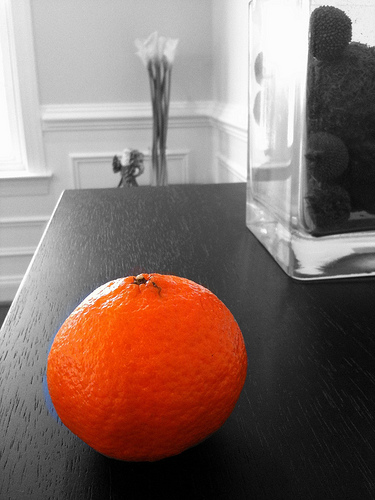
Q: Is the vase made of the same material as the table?
A: No, the vase is made of glass and the table is made of wood.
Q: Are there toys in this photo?
A: No, there are no toys.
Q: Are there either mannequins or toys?
A: No, there are no toys or mannequins.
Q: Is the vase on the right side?
A: Yes, the vase is on the right of the image.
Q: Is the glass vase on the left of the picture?
A: No, the vase is on the right of the image.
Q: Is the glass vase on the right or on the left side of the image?
A: The vase is on the right of the image.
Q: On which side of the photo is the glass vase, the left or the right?
A: The vase is on the right of the image.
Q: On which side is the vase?
A: The vase is on the right of the image.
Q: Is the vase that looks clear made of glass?
A: Yes, the vase is made of glass.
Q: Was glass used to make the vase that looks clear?
A: Yes, the vase is made of glass.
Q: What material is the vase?
A: The vase is made of glass.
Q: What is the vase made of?
A: The vase is made of glass.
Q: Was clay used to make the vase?
A: No, the vase is made of glass.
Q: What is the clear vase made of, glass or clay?
A: The vase is made of glass.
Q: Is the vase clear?
A: Yes, the vase is clear.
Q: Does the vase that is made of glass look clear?
A: Yes, the vase is clear.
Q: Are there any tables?
A: Yes, there is a table.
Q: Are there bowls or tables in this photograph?
A: Yes, there is a table.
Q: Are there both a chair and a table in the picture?
A: No, there is a table but no chairs.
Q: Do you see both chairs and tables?
A: No, there is a table but no chairs.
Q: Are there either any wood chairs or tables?
A: Yes, there is a wood table.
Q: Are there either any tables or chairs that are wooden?
A: Yes, the table is wooden.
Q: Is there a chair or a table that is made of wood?
A: Yes, the table is made of wood.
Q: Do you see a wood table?
A: Yes, there is a table that is made of wood.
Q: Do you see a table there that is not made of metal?
A: Yes, there is a table that is made of wood.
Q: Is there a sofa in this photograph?
A: No, there are no sofas.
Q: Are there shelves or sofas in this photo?
A: No, there are no sofas or shelves.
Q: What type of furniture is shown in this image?
A: The furniture is a table.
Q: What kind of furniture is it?
A: The piece of furniture is a table.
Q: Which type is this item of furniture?
A: This is a table.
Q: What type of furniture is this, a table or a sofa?
A: This is a table.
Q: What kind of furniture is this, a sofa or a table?
A: This is a table.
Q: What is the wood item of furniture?
A: The piece of furniture is a table.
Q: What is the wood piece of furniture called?
A: The piece of furniture is a table.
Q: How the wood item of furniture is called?
A: The piece of furniture is a table.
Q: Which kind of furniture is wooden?
A: The furniture is a table.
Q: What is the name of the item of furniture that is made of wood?
A: The piece of furniture is a table.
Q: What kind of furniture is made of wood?
A: The furniture is a table.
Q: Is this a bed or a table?
A: This is a table.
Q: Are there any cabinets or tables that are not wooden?
A: No, there is a table but it is wooden.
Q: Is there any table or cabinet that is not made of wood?
A: No, there is a table but it is made of wood.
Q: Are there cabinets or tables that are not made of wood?
A: No, there is a table but it is made of wood.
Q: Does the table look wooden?
A: Yes, the table is wooden.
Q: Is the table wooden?
A: Yes, the table is wooden.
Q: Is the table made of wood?
A: Yes, the table is made of wood.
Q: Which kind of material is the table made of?
A: The table is made of wood.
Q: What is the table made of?
A: The table is made of wood.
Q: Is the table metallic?
A: No, the table is wooden.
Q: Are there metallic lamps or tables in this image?
A: No, there is a table but it is wooden.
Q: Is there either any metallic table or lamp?
A: No, there is a table but it is wooden.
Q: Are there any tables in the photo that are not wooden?
A: No, there is a table but it is wooden.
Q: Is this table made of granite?
A: No, the table is made of wood.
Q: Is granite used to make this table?
A: No, the table is made of wood.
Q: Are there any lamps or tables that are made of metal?
A: No, there is a table but it is made of wood.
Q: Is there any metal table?
A: No, there is a table but it is made of wood.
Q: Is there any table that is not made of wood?
A: No, there is a table but it is made of wood.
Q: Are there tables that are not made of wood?
A: No, there is a table but it is made of wood.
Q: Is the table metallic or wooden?
A: The table is wooden.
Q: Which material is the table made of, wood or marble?
A: The table is made of wood.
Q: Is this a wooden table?
A: Yes, this is a wooden table.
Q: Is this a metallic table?
A: No, this is a wooden table.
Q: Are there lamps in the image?
A: No, there are no lamps.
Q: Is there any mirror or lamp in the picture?
A: No, there are no lamps or mirrors.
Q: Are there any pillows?
A: No, there are no pillows.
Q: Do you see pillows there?
A: No, there are no pillows.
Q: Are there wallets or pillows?
A: No, there are no pillows or wallets.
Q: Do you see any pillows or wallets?
A: No, there are no pillows or wallets.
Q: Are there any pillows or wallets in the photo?
A: No, there are no pillows or wallets.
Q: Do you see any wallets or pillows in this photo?
A: No, there are no pillows or wallets.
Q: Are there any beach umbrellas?
A: No, there are no beach umbrellas.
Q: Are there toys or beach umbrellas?
A: No, there are no beach umbrellas or toys.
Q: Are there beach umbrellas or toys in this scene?
A: No, there are no beach umbrellas or toys.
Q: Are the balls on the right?
A: Yes, the balls are on the right of the image.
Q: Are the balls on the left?
A: No, the balls are on the right of the image.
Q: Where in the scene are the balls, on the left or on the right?
A: The balls are on the right of the image.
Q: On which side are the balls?
A: The balls are on the right of the image.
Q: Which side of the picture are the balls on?
A: The balls are on the right of the image.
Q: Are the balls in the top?
A: Yes, the balls are in the top of the image.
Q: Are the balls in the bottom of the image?
A: No, the balls are in the top of the image.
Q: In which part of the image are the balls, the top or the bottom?
A: The balls are in the top of the image.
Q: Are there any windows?
A: Yes, there is a window.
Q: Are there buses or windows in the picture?
A: Yes, there is a window.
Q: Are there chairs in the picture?
A: No, there are no chairs.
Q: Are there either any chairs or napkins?
A: No, there are no chairs or napkins.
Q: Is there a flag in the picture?
A: No, there are no flags.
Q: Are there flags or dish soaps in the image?
A: No, there are no flags or dish soaps.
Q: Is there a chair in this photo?
A: No, there are no chairs.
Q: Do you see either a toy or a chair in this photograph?
A: No, there are no chairs or toys.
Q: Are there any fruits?
A: Yes, there is a fruit.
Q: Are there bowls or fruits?
A: Yes, there is a fruit.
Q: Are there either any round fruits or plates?
A: Yes, there is a round fruit.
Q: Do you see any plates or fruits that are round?
A: Yes, the fruit is round.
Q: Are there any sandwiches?
A: No, there are no sandwiches.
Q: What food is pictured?
A: The food is a fruit.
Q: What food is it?
A: The food is a fruit.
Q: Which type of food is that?
A: This is a fruit.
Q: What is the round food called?
A: The food is a fruit.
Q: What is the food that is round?
A: The food is a fruit.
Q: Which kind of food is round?
A: The food is a fruit.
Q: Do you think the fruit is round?
A: Yes, the fruit is round.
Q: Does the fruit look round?
A: Yes, the fruit is round.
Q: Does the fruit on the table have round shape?
A: Yes, the fruit is round.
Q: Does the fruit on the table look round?
A: Yes, the fruit is round.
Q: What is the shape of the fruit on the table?
A: The fruit is round.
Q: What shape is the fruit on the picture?
A: The fruit is round.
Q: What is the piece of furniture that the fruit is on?
A: The piece of furniture is a table.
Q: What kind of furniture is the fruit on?
A: The fruit is on the table.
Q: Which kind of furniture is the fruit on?
A: The fruit is on the table.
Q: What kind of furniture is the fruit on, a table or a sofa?
A: The fruit is on a table.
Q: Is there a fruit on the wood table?
A: Yes, there is a fruit on the table.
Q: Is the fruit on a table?
A: Yes, the fruit is on a table.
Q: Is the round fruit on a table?
A: Yes, the fruit is on a table.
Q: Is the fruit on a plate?
A: No, the fruit is on a table.